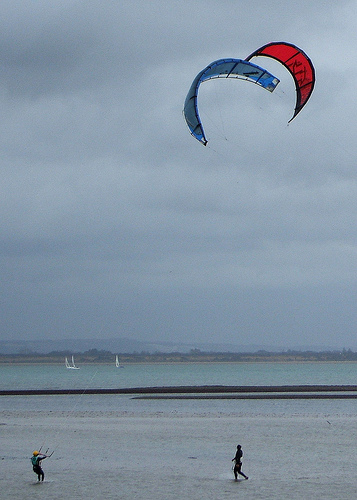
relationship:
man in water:
[228, 443, 249, 480] [3, 366, 356, 493]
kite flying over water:
[184, 56, 280, 145] [3, 366, 356, 493]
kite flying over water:
[242, 39, 314, 123] [3, 366, 356, 493]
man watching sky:
[228, 443, 249, 480] [2, 1, 355, 354]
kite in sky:
[242, 39, 314, 123] [2, 1, 355, 354]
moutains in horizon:
[5, 338, 356, 366] [2, 1, 356, 365]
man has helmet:
[27, 449, 54, 481] [32, 448, 41, 458]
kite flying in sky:
[242, 39, 314, 123] [2, 1, 355, 354]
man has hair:
[228, 443, 249, 480] [234, 443, 243, 451]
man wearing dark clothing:
[228, 443, 249, 480] [230, 450, 248, 477]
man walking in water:
[228, 443, 249, 480] [3, 366, 356, 493]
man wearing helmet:
[27, 449, 54, 481] [32, 448, 41, 458]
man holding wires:
[27, 449, 54, 481] [42, 62, 291, 454]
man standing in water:
[27, 449, 54, 481] [3, 366, 356, 493]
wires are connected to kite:
[42, 62, 291, 454] [184, 56, 280, 145]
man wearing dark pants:
[228, 443, 249, 480] [229, 462, 246, 480]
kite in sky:
[184, 56, 280, 145] [2, 1, 355, 354]